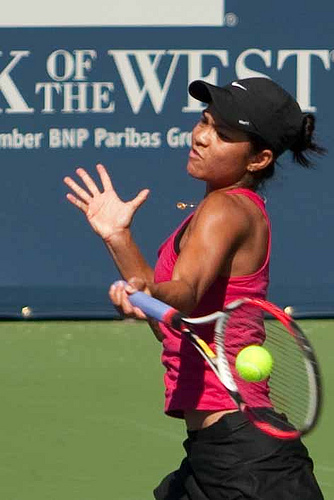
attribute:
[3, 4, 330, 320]
banner — blue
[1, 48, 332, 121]
bank of west — white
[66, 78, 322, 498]
woman — playing, grimacing, hitting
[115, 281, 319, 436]
racquet — left handed, pink, held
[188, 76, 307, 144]
cap — black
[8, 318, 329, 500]
court — green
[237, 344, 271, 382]
ball — about, yellow, green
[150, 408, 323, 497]
skort — black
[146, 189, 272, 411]
shirt — red, pink, sleeveless, magenta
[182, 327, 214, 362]
racket — yellow, used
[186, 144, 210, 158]
mouth — firm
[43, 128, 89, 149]
bnp — white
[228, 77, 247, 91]
nike — sponsor, white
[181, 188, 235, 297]
muscle — lean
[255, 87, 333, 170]
hairdo — daytime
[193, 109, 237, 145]
eyes — focused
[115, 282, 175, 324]
grip — blue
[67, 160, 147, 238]
palm — open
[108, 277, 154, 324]
hand — curled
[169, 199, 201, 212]
pendant — flying, gold